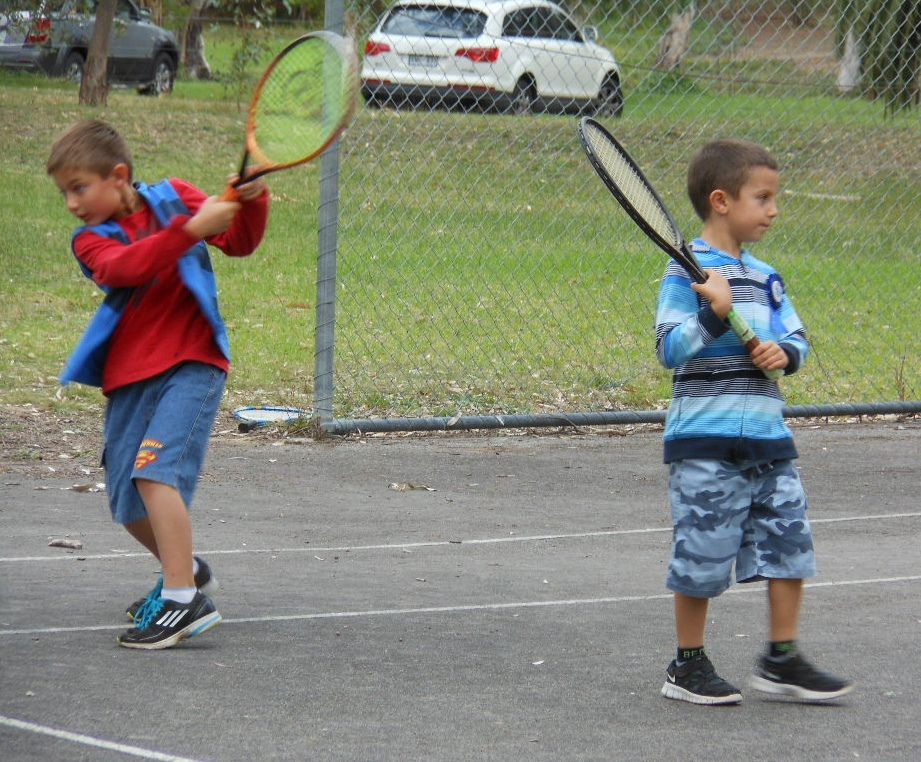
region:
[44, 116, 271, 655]
the boy swinging the racquet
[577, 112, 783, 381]
the black frame of the racquet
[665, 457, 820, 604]
the blue shorts of the boy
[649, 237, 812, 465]
the blue jacket of the boy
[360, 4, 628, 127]
the white car in the parking lot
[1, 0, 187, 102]
the silver car in the parking lot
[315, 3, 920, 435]
the chainlink fence behind the boys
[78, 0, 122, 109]
the trunk of the tree in the field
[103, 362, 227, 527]
the jean shorts on the boy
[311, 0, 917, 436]
Chain link fence by tennis court.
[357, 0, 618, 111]
A white car parked near the court.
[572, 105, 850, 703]
Boy in striped blue shirt holding a tennis racket.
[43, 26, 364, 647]
A boy in a red shirt with a tennis racket.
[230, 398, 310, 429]
A tennis racket laying on the ground.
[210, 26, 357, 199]
Brown tennis racket held by boy in red top.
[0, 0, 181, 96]
A grey car parked near the court.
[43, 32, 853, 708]
the boys holding the rackets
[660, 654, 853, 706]
the shoes are black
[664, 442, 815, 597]
the camo shorts are blue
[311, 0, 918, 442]
the chain link fence is gray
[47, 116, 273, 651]
the boy wearing a long sleeved shirt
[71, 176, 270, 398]
the long sleeved shirt is red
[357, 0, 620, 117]
the white suv is parked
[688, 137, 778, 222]
the short hair is brown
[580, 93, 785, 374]
a young boy holding a tennis racket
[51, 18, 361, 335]
a young boy swinging a tennis racket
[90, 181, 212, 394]
a young boy wearing a red shirt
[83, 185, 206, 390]
a young boy wearing a blue vest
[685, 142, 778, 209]
a young boy with brown hair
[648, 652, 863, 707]
a young boy wearing black shoes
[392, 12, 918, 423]
a chain link fence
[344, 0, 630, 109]
a parked white vehicle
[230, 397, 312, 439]
a tennis racket on the ground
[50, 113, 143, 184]
a young boy with short hair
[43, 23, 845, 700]
two boys holding tennis rackets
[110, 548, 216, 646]
black shoes with blue laces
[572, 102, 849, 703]
boy holding black tennis racket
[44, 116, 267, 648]
boy wearing red shirt and blue vest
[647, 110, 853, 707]
boy wearing blue camouflage shorts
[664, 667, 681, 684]
white nike logo on side of shoe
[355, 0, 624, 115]
parked white SUV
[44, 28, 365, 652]
boy swinging a tennis racket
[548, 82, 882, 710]
boy holding a racket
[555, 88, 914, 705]
boy wearing a blue shirt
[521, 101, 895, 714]
boy wearing blue shorts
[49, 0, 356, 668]
boy holding a racket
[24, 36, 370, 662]
boy wearing red shirt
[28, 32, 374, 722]
boy wearing blue shorts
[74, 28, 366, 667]
boy wearing white socks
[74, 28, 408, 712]
boy wearing black shoes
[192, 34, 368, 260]
an orange and black tennis racket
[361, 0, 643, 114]
a small white suv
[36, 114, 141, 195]
short cut brown hair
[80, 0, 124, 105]
a brown tree trunk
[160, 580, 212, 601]
a boy's blue and white sock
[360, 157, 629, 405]
a section of green grass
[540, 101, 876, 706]
boy holding a tennis racket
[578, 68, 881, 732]
boy wearing blue shirt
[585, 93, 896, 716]
boy wearing shorts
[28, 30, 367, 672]
boy wearing red shirt